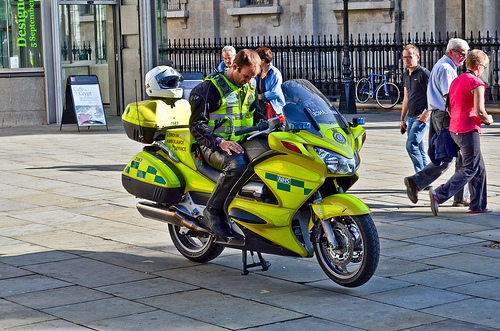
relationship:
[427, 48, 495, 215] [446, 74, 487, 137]
woman wearing shirt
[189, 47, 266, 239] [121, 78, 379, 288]
man sitting on motorcycle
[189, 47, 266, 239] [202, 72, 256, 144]
man wearing vest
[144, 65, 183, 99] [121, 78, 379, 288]
helmet on back of motorcycle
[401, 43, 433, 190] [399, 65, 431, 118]
man wearing shirt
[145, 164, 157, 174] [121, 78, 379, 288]
rectangle design on motorcycle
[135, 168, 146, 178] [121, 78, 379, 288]
rectangle design on motorcycle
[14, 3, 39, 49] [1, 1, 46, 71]
letters on window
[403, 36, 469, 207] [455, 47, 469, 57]
man wearing sunglasses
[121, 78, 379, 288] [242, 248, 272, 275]
motorcycle on stand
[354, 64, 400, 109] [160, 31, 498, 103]
bike leaning on gate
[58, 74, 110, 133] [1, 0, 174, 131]
sign in front of store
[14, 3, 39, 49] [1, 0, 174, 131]
letters on store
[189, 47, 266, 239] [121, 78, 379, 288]
man on motorcycle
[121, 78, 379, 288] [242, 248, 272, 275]
motorcycle has stand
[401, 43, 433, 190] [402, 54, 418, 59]
man wearing glasses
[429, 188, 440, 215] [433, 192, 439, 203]
shoe has stripes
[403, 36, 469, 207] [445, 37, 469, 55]
man has hair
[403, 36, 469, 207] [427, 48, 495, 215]
man walking with woman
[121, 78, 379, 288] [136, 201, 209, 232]
motorcycle has muffler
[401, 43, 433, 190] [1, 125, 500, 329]
man walking on walkway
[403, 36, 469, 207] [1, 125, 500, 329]
man walking on walkway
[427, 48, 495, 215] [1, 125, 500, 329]
woman walking on walkway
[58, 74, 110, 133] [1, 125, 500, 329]
sign on walkway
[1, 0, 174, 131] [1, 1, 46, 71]
store has window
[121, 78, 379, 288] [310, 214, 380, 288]
motorcycle has front wheel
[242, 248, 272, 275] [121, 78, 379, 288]
stand under motorcycle